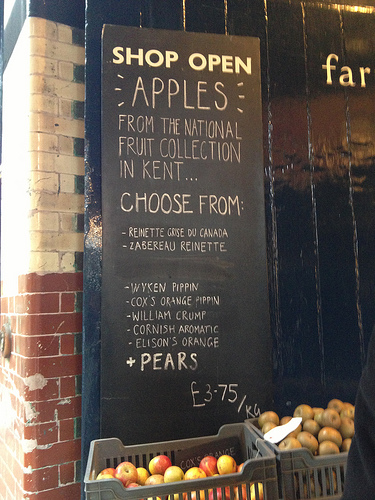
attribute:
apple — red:
[146, 454, 172, 478]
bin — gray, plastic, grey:
[82, 421, 284, 499]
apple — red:
[198, 454, 221, 476]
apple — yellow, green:
[215, 451, 238, 476]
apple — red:
[114, 459, 139, 486]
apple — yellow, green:
[182, 466, 209, 487]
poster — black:
[97, 22, 279, 454]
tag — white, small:
[259, 414, 305, 446]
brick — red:
[9, 290, 64, 319]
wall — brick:
[0, 0, 90, 499]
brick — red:
[12, 312, 89, 339]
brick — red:
[9, 331, 65, 361]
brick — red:
[7, 374, 64, 406]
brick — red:
[11, 464, 64, 495]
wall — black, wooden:
[83, 0, 374, 499]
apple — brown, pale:
[256, 410, 279, 429]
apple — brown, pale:
[275, 435, 304, 456]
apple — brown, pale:
[292, 403, 317, 424]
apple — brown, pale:
[316, 426, 346, 449]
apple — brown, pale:
[319, 408, 342, 431]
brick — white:
[15, 16, 62, 45]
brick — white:
[13, 38, 90, 70]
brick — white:
[16, 54, 62, 81]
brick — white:
[13, 92, 64, 120]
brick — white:
[16, 130, 64, 155]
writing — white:
[109, 44, 265, 421]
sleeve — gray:
[338, 322, 374, 499]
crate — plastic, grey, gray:
[244, 397, 373, 498]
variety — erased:
[111, 257, 240, 284]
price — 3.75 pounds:
[185, 375, 267, 426]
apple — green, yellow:
[134, 462, 150, 486]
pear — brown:
[319, 440, 340, 458]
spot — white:
[83, 213, 115, 262]